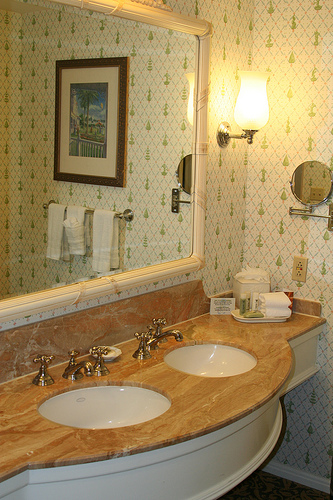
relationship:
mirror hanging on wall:
[287, 151, 331, 211] [243, 0, 332, 476]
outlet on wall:
[288, 253, 307, 282] [243, 0, 332, 476]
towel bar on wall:
[42, 199, 134, 220] [22, 0, 199, 293]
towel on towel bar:
[44, 202, 69, 261] [40, 196, 136, 223]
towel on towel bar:
[59, 205, 88, 256] [40, 196, 136, 223]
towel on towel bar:
[89, 208, 119, 273] [40, 196, 136, 223]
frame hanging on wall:
[51, 54, 130, 185] [22, 0, 199, 293]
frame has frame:
[51, 54, 130, 185] [51, 54, 130, 185]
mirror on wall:
[0, 19, 232, 289] [1, 0, 254, 329]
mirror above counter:
[0, 19, 232, 289] [0, 298, 326, 500]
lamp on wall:
[215, 72, 269, 148] [1, 0, 254, 329]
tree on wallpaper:
[287, 51, 296, 65] [4, 1, 331, 322]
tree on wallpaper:
[284, 90, 292, 100] [4, 1, 331, 322]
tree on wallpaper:
[280, 155, 290, 166] [4, 1, 331, 322]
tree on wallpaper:
[280, 191, 288, 201] [4, 1, 331, 322]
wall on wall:
[1, 2, 332, 477] [1, 2, 332, 477]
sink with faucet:
[29, 356, 195, 462] [61, 346, 95, 380]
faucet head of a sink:
[56, 349, 102, 378] [45, 373, 173, 429]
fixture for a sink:
[32, 353, 54, 388] [32, 379, 175, 430]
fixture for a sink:
[88, 345, 111, 376] [32, 379, 175, 430]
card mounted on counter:
[208, 296, 234, 315] [1, 300, 325, 483]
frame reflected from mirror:
[51, 54, 130, 185] [2, 2, 217, 314]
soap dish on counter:
[86, 342, 122, 362] [0, 290, 313, 478]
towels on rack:
[255, 293, 289, 306] [250, 285, 291, 317]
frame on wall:
[51, 54, 130, 185] [5, 28, 331, 256]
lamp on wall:
[215, 72, 269, 148] [205, 5, 331, 292]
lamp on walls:
[212, 52, 299, 210] [263, 24, 320, 68]